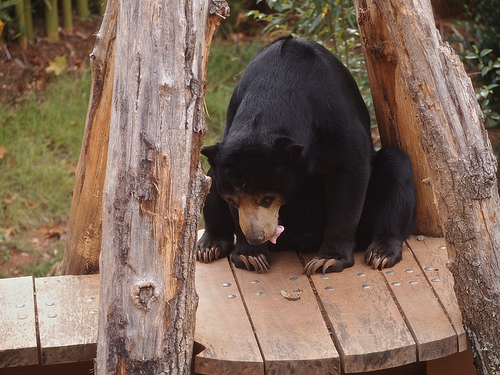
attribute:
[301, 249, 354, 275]
paw — bear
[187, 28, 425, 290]
bear is — black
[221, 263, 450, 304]
screws — metal, round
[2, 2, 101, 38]
bamboo — green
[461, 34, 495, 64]
leave — green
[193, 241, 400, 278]
claws — long, bear, brown, sharp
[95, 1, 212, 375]
trunk — peeling off, damaged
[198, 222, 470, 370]
bridge — oval, wooden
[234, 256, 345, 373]
board — rectangular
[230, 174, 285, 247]
face — light color, pale, black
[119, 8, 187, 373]
bark — rubbed off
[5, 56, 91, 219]
grass — green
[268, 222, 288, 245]
thing — mouth, pink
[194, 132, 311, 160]
ears — small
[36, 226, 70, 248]
leaf — grass